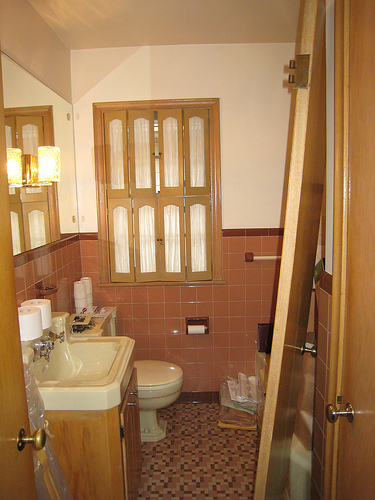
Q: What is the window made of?
A: Wood and glass.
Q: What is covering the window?
A: Shutters.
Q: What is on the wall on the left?
A: A mirror.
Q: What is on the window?
A: Shutters.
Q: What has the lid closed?
A: The toilet.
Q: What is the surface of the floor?
A: Tile.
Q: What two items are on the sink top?
A: Toilet paper.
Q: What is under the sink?
A: A wood cabinet.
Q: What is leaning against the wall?
A: A door.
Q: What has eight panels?
A: The window shutters.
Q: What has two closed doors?
A: The cabinet under the sink.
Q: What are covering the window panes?
A: Curtains.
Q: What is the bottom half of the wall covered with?
A: Tile.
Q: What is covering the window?
A: Shutters.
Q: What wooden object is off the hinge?
A: Door.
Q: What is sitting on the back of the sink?
A: Rolls of toilet paper.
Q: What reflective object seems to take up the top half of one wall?
A: A mirror.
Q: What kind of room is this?
A: Bathroom.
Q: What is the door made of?
A: Wood.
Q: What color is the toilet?
A: White.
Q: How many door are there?
A: Three.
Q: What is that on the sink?
A: Toilet tissue.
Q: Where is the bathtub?
A: Behind the door.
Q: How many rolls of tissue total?
A: Three.